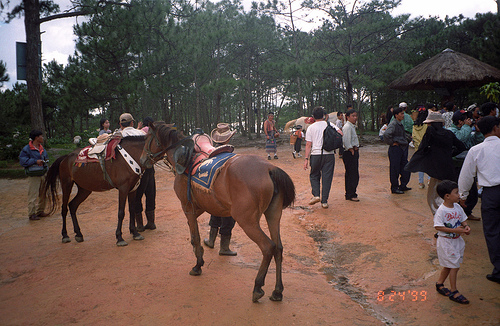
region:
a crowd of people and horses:
[11, 78, 498, 312]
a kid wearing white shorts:
[430, 178, 473, 304]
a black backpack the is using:
[321, 123, 342, 151]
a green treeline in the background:
[64, 2, 426, 64]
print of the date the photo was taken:
[374, 288, 428, 303]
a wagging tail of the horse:
[268, 163, 295, 208]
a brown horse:
[137, 116, 294, 305]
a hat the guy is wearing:
[208, 120, 236, 142]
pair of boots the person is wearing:
[201, 226, 237, 257]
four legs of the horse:
[58, 194, 144, 246]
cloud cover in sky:
[0, 0, 498, 77]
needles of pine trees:
[46, 4, 497, 116]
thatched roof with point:
[398, 45, 496, 87]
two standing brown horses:
[40, 117, 295, 301]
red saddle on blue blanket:
[187, 130, 227, 187]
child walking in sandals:
[430, 181, 472, 304]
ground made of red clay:
[0, 142, 493, 324]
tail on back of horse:
[36, 152, 68, 214]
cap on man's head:
[115, 111, 136, 129]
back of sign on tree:
[13, 40, 41, 81]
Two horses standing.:
[57, 130, 349, 324]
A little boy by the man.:
[431, 175, 476, 322]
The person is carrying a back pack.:
[310, 115, 343, 154]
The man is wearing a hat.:
[199, 97, 239, 142]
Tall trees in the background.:
[71, 22, 373, 136]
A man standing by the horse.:
[196, 117, 241, 263]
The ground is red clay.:
[58, 240, 155, 324]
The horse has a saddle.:
[181, 124, 242, 172]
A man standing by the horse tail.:
[14, 129, 54, 222]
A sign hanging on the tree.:
[2, 35, 54, 81]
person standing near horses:
[300, 99, 344, 211]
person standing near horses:
[430, 179, 467, 306]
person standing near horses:
[381, 103, 417, 203]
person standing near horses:
[340, 106, 368, 205]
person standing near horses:
[15, 120, 55, 223]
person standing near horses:
[114, 108, 159, 237]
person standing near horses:
[92, 114, 114, 149]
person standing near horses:
[198, 117, 244, 260]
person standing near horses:
[260, 110, 281, 162]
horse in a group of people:
[132, 115, 295, 309]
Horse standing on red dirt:
[121, 115, 315, 316]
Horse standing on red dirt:
[31, 96, 158, 233]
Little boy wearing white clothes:
[413, 180, 485, 298]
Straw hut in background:
[401, 32, 490, 92]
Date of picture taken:
[368, 276, 439, 313]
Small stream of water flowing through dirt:
[285, 200, 422, 322]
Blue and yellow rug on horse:
[184, 135, 259, 189]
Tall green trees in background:
[63, 13, 497, 235]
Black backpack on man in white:
[310, 120, 342, 160]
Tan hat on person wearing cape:
[416, 108, 446, 120]